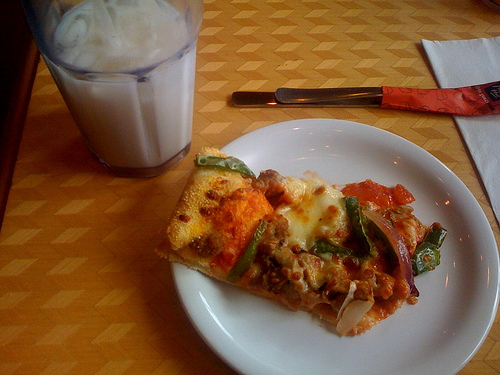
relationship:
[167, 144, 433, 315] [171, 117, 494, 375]
pizza on plate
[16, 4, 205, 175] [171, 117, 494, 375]
cup near plate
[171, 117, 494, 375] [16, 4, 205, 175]
plate near cup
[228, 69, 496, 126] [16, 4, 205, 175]
silverware near cup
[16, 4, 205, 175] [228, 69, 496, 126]
cup near silverware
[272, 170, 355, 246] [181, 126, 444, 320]
cheese on pizza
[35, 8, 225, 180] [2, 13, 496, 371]
glass on table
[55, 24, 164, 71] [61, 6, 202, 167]
ice in drink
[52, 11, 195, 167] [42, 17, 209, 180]
milk in cup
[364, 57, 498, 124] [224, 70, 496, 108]
paper around utensils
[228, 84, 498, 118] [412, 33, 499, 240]
utensils placed on napkin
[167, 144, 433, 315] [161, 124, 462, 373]
pizza on plate